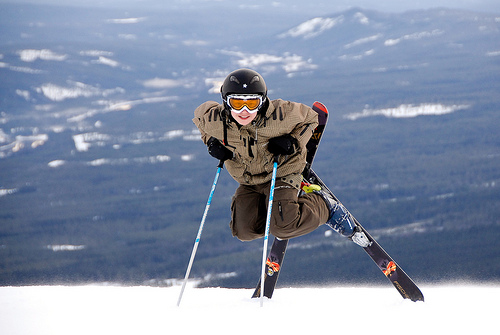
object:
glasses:
[222, 92, 264, 114]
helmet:
[219, 67, 270, 125]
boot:
[315, 190, 360, 240]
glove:
[265, 133, 300, 158]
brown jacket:
[190, 96, 320, 186]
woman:
[189, 67, 358, 244]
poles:
[253, 162, 279, 310]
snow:
[0, 283, 498, 334]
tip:
[311, 101, 329, 115]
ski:
[299, 168, 425, 303]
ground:
[0, 0, 500, 335]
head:
[222, 92, 263, 126]